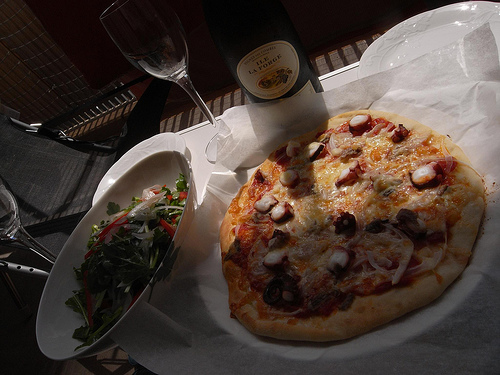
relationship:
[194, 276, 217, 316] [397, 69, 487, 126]
plate under paper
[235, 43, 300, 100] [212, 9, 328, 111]
label stuck on bottle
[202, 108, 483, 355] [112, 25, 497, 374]
pizza on paper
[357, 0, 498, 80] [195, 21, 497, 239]
plate under paper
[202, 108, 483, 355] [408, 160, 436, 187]
pizza with onion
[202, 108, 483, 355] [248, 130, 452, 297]
pizza with cheese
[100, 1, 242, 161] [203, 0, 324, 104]
glass by wine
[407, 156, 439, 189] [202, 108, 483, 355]
radish on pizza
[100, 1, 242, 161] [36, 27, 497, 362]
glass on table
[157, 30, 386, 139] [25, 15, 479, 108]
shadow on floor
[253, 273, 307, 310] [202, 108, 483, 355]
olive on pizza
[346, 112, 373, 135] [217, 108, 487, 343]
topping for pizza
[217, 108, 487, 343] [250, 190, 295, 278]
pizza has meat